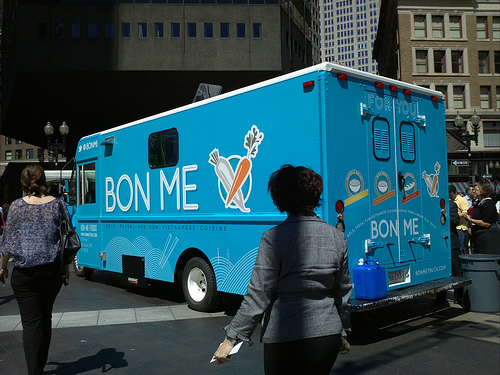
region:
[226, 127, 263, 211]
an orange carrot is on the truck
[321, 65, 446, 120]
There are five lights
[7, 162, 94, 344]
the woman is wearing black pants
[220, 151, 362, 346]
The woman has a gray shirt on.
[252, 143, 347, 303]
The woman has short black hair.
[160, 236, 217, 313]
The wheel has white rim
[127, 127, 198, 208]
the window is black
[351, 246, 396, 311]
A blue container sits on the back tailgate of the tckru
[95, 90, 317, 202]
The truck has a white roof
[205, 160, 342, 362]
The woman is holding paper in her left hand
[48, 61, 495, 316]
Blue truck parked in parking lot.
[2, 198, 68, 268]
Woman dressed in gray sweater.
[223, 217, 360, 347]
Woman dressed in long sleeve gray jacket.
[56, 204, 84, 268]
Woman carrying black purse over shoulder.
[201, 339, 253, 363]
Woman carrying white envelope in hand.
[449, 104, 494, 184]
Lamp post standing in parking lot.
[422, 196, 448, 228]
Break and signal lights on back of truck.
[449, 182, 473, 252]
Man standing on side of truck wearing yellow shirt.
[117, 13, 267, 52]
Windows on side of building.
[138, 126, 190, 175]
Window on side of blue truck.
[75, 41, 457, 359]
the car is blue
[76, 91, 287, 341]
the car is blue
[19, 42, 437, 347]
blue food truck parked in street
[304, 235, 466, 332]
5-gallon water jug on back bumper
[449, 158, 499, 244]
line to order food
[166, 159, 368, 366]
lady in business casual attire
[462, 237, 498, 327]
trash bin next to truck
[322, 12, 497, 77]
windows to apartments across from food truck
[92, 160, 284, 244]
food truck says "bon me" so it must be good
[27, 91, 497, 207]
street lights on either side of the truck that are not working yet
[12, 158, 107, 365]
lady carrying purse over her shoulder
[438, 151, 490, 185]
one way sign on light pole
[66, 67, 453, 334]
a baby blue truck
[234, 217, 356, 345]
woman wearing a gray jacket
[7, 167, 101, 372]
woman walking in the street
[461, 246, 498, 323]
a gray garbage can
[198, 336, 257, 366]
woman holding a white envelope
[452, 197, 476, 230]
man wearing a yellow shirt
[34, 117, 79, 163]
streetlamps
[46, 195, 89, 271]
a black bag on woman's shoulder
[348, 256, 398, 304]
a blue plastic jug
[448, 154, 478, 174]
a one way sign